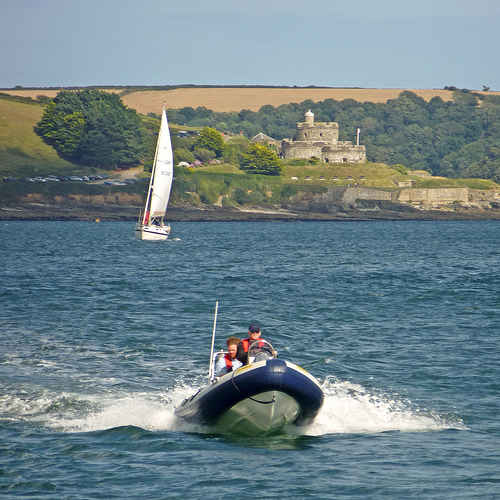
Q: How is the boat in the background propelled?
A: Sail.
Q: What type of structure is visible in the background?
A: Stone castle.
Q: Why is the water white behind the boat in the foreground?
A: Wake from motor.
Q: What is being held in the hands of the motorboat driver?
A: Steering wheel.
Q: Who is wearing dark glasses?
A: Driver of motorboat.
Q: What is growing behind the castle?
A: Trees.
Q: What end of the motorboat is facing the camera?
A: Bow.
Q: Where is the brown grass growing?
A: The hills above the trees.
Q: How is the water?
A: Choppy.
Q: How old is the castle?
A: Old.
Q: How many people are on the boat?
A: 2.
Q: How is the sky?
A: Clear.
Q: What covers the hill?
A: Trees and farmland.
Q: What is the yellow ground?
A: Farmland.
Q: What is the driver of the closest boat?
A: Hat.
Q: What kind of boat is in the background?
A: Sailboat.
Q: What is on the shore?
A: Building.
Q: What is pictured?
A: A raft watercraft.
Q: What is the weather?
A: Sunny and warm.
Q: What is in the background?
A: A sailboat.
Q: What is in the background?
A: A grassy tree covered hillside.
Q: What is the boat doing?
A: Speeding through the water.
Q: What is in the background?
A: A castle.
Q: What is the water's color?
A: Clear blue.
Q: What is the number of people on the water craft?
A: Two.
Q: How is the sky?
A: Clear and blue.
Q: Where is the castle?
A: The hillside.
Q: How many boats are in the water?
A: Two.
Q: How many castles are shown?
A: One.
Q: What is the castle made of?
A: Stone.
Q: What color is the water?
A: Blue.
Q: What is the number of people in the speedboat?
A: Two.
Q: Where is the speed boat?
A: The water.